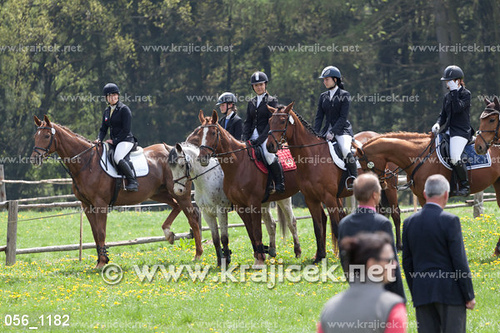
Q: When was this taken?
A: Daytime.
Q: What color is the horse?
A: Brown.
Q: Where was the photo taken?
A: In a park.